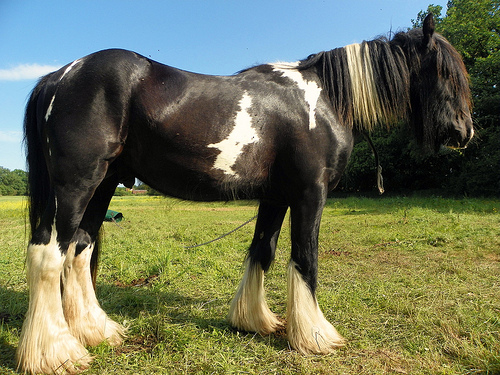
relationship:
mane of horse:
[301, 29, 420, 133] [12, 19, 480, 367]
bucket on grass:
[101, 207, 123, 224] [0, 190, 498, 374]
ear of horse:
[417, 11, 440, 46] [12, 19, 480, 367]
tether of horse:
[195, 199, 262, 251] [96, 63, 473, 240]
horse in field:
[12, 19, 480, 367] [1, 194, 498, 373]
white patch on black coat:
[197, 88, 264, 181] [75, 56, 284, 191]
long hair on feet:
[224, 250, 346, 358] [16, 301, 342, 372]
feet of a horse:
[16, 314, 87, 372] [12, 19, 480, 367]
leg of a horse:
[285, 155, 349, 357] [12, 19, 480, 367]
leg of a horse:
[226, 195, 283, 333] [12, 19, 480, 367]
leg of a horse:
[11, 138, 112, 370] [12, 19, 480, 367]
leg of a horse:
[61, 162, 126, 349] [12, 19, 480, 367]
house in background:
[116, 177, 141, 190] [18, 10, 484, 347]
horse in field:
[12, 19, 480, 367] [346, 176, 481, 350]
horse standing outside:
[12, 19, 480, 367] [6, 4, 471, 373]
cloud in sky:
[8, 49, 85, 112] [125, 12, 307, 51]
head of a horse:
[406, 11, 476, 156] [12, 19, 480, 367]